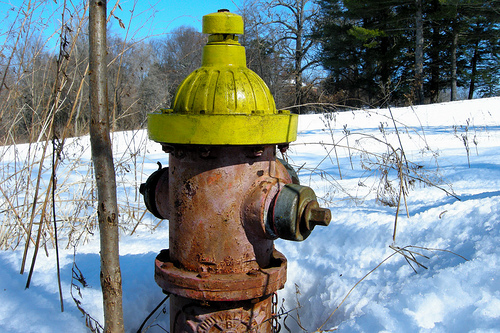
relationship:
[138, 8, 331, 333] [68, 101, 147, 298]
fire hydrant by tree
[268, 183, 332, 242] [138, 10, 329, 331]
arm on side of fire hydrant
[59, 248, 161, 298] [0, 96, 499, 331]
shadow on snow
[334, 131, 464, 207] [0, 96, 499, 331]
branch sticking out of snow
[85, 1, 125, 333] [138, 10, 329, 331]
tree next to fire hydrant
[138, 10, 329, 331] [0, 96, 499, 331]
fire hydrant in snow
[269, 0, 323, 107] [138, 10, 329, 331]
tree behind fire hydrant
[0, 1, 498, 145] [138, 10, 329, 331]
woods behind fire hydrant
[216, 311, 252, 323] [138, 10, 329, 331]
word on fire hydrant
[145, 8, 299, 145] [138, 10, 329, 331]
top on fire hydrant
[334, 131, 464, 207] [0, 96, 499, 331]
branch in snow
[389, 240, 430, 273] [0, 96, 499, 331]
branch in snow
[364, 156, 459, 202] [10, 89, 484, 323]
branch in snow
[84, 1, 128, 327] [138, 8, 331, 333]
tree by fire hydrant